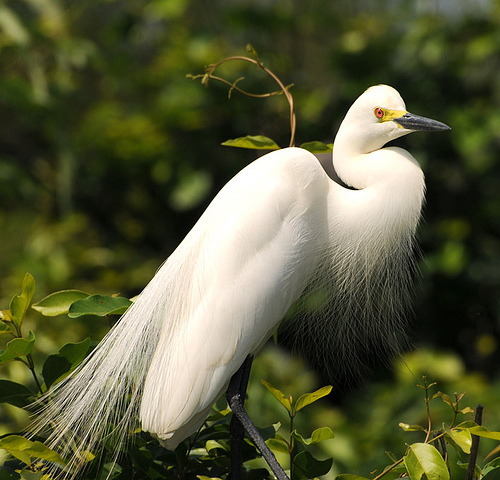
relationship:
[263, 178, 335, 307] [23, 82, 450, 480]
chest of bird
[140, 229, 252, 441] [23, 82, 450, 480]
wing of bird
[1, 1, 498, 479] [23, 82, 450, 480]
trees behind bird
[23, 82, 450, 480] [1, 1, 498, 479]
bird near trees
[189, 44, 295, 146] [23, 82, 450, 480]
twig behind bird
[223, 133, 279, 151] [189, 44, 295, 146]
leaf on twig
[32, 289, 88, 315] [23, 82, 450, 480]
leaf near bird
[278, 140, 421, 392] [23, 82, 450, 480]
neck of bird